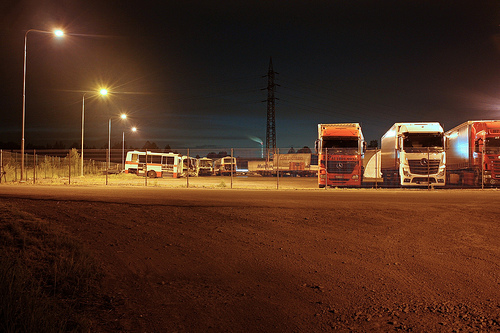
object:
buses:
[312, 120, 365, 190]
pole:
[2, 149, 9, 185]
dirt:
[0, 187, 500, 333]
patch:
[3, 189, 110, 331]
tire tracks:
[377, 196, 499, 333]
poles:
[18, 25, 38, 180]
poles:
[106, 106, 114, 174]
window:
[400, 132, 444, 152]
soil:
[0, 186, 500, 333]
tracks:
[339, 289, 500, 331]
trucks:
[118, 145, 188, 180]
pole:
[78, 90, 88, 177]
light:
[94, 82, 114, 97]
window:
[320, 137, 362, 158]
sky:
[0, 0, 500, 120]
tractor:
[309, 119, 365, 192]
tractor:
[378, 114, 451, 193]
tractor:
[444, 117, 498, 189]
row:
[312, 115, 498, 192]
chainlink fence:
[1, 147, 496, 189]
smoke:
[241, 134, 265, 159]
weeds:
[0, 162, 94, 183]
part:
[301, 267, 391, 323]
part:
[47, 236, 136, 330]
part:
[417, 271, 492, 331]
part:
[260, 220, 351, 256]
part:
[421, 205, 486, 246]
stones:
[391, 259, 400, 266]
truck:
[377, 118, 451, 188]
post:
[320, 145, 333, 187]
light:
[50, 26, 69, 40]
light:
[120, 110, 128, 120]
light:
[130, 122, 138, 133]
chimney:
[262, 48, 278, 162]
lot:
[0, 98, 497, 199]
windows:
[136, 153, 175, 165]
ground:
[0, 181, 500, 333]